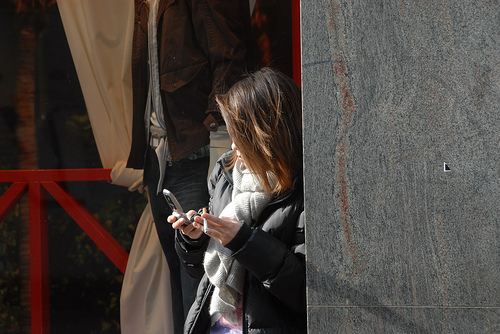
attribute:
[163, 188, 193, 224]
cell phone — a flip phone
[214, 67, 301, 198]
hair — brown, short, light, dark brown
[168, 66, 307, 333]
woman — smoking, brunette, texting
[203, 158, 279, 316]
scarf — white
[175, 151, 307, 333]
coat — black, a bubble coat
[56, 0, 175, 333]
cloth — white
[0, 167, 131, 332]
railing — red, painted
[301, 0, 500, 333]
wall — concrete, gray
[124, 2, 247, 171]
jacket — brown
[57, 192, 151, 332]
bush — green